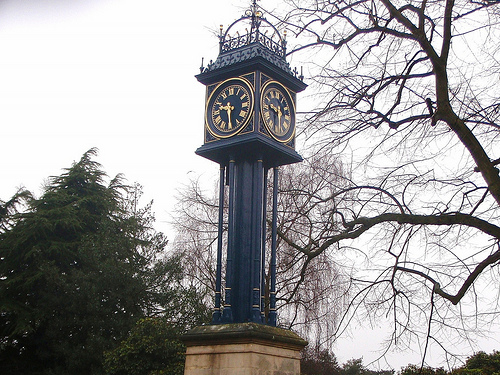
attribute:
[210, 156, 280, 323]
pole — black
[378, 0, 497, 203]
branch — dry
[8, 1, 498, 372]
sky — light, gray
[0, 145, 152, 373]
tree — thick, dark 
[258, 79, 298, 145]
clock — Gold, black 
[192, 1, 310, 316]
clock tower — Black , gold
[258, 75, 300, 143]
clock — big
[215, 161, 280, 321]
pole — thick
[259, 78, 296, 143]
clock — gold 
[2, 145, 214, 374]
tree — green 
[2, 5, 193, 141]
sky — white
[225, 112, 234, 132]
hand — minute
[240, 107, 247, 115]
numerals — on the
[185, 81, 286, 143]
clock — has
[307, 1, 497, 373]
tree — leafless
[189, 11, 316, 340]
clock tower — black 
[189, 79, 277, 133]
clock — indicating its 9:30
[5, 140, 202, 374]
trees — green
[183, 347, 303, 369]
base — brown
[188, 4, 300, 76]
top — decorative